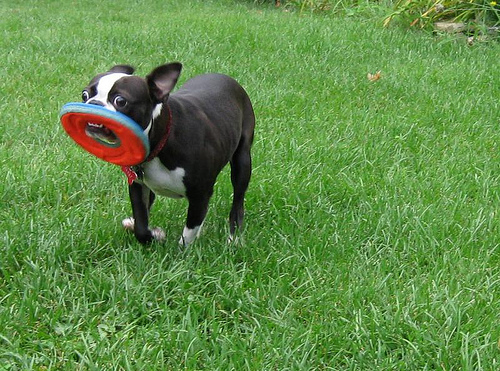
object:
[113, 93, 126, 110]
eye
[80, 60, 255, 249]
dog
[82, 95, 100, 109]
nose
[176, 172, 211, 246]
leg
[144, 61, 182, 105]
ear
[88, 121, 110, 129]
teeth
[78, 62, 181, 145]
head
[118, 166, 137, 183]
tag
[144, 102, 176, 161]
collar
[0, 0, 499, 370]
grass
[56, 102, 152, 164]
toy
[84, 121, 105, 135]
mouth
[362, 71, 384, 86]
leaf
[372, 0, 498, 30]
leaves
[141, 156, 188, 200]
chest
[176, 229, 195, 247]
foot